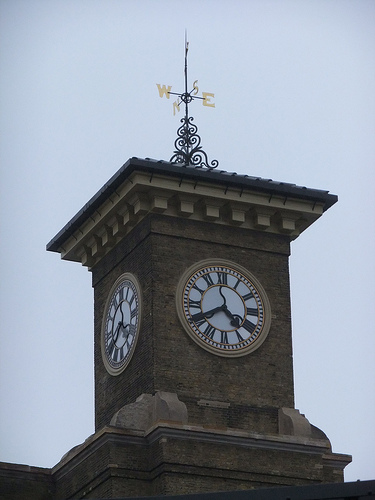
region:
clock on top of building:
[175, 263, 273, 357]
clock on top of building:
[92, 271, 155, 370]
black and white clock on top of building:
[177, 256, 271, 357]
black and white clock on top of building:
[99, 278, 141, 370]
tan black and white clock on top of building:
[168, 253, 279, 358]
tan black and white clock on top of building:
[92, 271, 149, 380]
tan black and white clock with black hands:
[88, 266, 156, 399]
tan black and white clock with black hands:
[175, 247, 271, 357]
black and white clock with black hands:
[174, 260, 285, 380]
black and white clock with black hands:
[86, 263, 144, 380]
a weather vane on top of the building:
[150, 26, 221, 157]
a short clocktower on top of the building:
[47, 158, 340, 455]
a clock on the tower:
[178, 250, 272, 367]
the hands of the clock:
[195, 283, 242, 329]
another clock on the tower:
[95, 280, 146, 376]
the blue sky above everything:
[6, 5, 374, 161]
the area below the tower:
[54, 400, 373, 498]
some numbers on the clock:
[214, 270, 257, 316]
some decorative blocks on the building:
[109, 392, 184, 433]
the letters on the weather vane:
[150, 82, 215, 110]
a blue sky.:
[17, 36, 152, 126]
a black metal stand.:
[154, 124, 214, 161]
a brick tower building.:
[153, 360, 277, 394]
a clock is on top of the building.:
[154, 246, 275, 358]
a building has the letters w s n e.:
[135, 62, 229, 114]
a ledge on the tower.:
[92, 405, 362, 470]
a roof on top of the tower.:
[0, 422, 95, 469]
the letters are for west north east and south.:
[130, 51, 240, 160]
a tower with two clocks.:
[75, 248, 276, 376]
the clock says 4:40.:
[165, 251, 281, 366]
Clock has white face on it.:
[189, 261, 281, 394]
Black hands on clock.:
[175, 269, 267, 371]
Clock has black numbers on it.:
[187, 254, 273, 365]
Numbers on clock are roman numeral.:
[180, 252, 272, 363]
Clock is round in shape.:
[179, 250, 271, 381]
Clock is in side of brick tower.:
[168, 255, 269, 377]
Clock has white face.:
[81, 270, 167, 405]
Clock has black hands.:
[98, 306, 156, 374]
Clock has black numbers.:
[97, 283, 186, 409]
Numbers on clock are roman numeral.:
[85, 276, 147, 387]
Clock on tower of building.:
[177, 251, 272, 360]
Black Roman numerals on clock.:
[177, 258, 271, 353]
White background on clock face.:
[177, 260, 270, 355]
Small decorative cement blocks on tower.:
[152, 189, 297, 237]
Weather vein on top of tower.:
[152, 20, 232, 168]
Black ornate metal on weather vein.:
[175, 38, 215, 169]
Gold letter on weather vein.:
[152, 69, 176, 103]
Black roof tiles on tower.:
[130, 146, 355, 213]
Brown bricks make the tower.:
[158, 356, 294, 405]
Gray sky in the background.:
[321, 307, 371, 389]